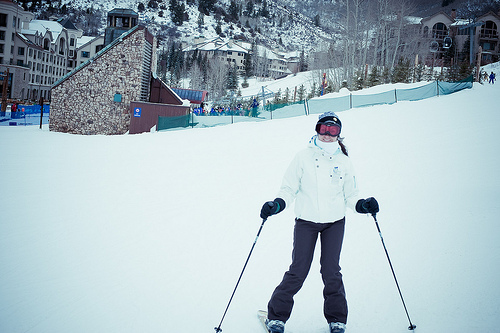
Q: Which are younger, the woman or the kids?
A: The kids are younger than the woman.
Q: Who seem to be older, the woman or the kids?
A: The woman are older than the kids.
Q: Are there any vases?
A: No, there are no vases.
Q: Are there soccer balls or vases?
A: No, there are no vases or soccer balls.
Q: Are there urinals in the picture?
A: No, there are no urinals.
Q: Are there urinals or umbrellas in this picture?
A: No, there are no urinals or umbrellas.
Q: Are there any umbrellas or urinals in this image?
A: No, there are no urinals or umbrellas.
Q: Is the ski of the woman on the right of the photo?
A: Yes, the ski is on the right of the image.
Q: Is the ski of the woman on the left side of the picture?
A: No, the ski is on the right of the image.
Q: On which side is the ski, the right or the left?
A: The ski is on the right of the image.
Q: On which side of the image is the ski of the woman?
A: The ski is on the right of the image.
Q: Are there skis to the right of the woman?
A: Yes, there is a ski to the right of the woman.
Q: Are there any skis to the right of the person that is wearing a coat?
A: Yes, there is a ski to the right of the woman.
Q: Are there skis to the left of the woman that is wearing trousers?
A: No, the ski is to the right of the woman.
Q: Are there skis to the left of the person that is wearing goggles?
A: No, the ski is to the right of the woman.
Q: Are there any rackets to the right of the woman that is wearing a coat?
A: No, there is a ski to the right of the woman.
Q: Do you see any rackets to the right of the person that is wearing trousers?
A: No, there is a ski to the right of the woman.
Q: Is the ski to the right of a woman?
A: Yes, the ski is to the right of a woman.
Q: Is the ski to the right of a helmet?
A: No, the ski is to the right of a woman.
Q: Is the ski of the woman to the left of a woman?
A: No, the ski is to the right of a woman.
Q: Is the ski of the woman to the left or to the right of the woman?
A: The ski is to the right of the woman.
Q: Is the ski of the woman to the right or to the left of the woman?
A: The ski is to the right of the woman.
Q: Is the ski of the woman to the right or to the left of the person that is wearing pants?
A: The ski is to the right of the woman.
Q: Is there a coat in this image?
A: Yes, there is a coat.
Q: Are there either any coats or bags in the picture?
A: Yes, there is a coat.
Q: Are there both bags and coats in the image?
A: No, there is a coat but no bags.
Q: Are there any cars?
A: No, there are no cars.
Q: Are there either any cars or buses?
A: No, there are no cars or buses.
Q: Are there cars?
A: No, there are no cars.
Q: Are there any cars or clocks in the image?
A: No, there are no cars or clocks.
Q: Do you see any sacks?
A: No, there are no sacks.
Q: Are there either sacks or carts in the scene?
A: No, there are no sacks or carts.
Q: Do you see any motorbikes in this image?
A: No, there are no motorbikes.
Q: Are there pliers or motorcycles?
A: No, there are no motorcycles or pliers.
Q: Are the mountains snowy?
A: Yes, the mountains are snowy.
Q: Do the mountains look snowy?
A: Yes, the mountains are snowy.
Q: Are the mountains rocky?
A: No, the mountains are snowy.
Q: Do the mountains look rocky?
A: No, the mountains are snowy.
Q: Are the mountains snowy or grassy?
A: The mountains are snowy.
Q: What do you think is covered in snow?
A: The mountains are covered in snow.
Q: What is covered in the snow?
A: The mountains are covered in snow.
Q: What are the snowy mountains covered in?
A: The mountains are covered in snow.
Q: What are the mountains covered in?
A: The mountains are covered in snow.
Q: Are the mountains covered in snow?
A: Yes, the mountains are covered in snow.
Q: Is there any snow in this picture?
A: Yes, there is snow.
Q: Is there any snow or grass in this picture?
A: Yes, there is snow.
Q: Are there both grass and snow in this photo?
A: No, there is snow but no grass.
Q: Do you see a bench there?
A: No, there are no benches.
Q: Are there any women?
A: Yes, there is a woman.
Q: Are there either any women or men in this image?
A: Yes, there is a woman.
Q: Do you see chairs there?
A: No, there are no chairs.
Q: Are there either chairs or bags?
A: No, there are no chairs or bags.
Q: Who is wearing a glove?
A: The woman is wearing a glove.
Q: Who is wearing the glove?
A: The woman is wearing a glove.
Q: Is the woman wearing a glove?
A: Yes, the woman is wearing a glove.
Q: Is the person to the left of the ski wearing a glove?
A: Yes, the woman is wearing a glove.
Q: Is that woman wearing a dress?
A: No, the woman is wearing a glove.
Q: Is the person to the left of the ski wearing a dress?
A: No, the woman is wearing a glove.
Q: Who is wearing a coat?
A: The woman is wearing a coat.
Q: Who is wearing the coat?
A: The woman is wearing a coat.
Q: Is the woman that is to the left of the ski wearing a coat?
A: Yes, the woman is wearing a coat.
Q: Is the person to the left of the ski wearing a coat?
A: Yes, the woman is wearing a coat.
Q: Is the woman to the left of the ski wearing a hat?
A: No, the woman is wearing a coat.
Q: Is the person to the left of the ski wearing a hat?
A: No, the woman is wearing a coat.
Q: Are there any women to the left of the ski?
A: Yes, there is a woman to the left of the ski.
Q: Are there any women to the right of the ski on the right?
A: No, the woman is to the left of the ski.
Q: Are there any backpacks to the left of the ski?
A: No, there is a woman to the left of the ski.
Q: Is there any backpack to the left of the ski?
A: No, there is a woman to the left of the ski.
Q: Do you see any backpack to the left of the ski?
A: No, there is a woman to the left of the ski.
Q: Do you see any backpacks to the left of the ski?
A: No, there is a woman to the left of the ski.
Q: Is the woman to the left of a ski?
A: Yes, the woman is to the left of a ski.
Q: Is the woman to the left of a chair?
A: No, the woman is to the left of a ski.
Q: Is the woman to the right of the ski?
A: No, the woman is to the left of the ski.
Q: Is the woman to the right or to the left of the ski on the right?
A: The woman is to the left of the ski.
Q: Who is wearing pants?
A: The woman is wearing pants.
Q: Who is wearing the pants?
A: The woman is wearing pants.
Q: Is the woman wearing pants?
A: Yes, the woman is wearing pants.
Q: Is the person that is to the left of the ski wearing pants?
A: Yes, the woman is wearing pants.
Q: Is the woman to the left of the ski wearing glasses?
A: No, the woman is wearing pants.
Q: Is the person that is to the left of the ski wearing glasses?
A: No, the woman is wearing pants.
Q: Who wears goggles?
A: The woman wears goggles.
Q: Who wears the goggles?
A: The woman wears goggles.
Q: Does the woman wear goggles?
A: Yes, the woman wears goggles.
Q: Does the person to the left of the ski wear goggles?
A: Yes, the woman wears goggles.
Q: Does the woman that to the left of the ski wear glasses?
A: No, the woman wears goggles.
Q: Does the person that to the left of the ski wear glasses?
A: No, the woman wears goggles.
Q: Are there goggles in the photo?
A: Yes, there are goggles.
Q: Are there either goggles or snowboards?
A: Yes, there are goggles.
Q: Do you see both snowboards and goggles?
A: No, there are goggles but no snowboards.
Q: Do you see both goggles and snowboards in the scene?
A: No, there are goggles but no snowboards.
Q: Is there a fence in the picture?
A: Yes, there is a fence.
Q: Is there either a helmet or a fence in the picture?
A: Yes, there is a fence.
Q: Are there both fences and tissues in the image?
A: No, there is a fence but no tissues.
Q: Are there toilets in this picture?
A: No, there are no toilets.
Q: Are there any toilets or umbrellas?
A: No, there are no toilets or umbrellas.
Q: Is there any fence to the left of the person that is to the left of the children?
A: Yes, there is a fence to the left of the person.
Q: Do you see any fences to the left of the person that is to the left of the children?
A: Yes, there is a fence to the left of the person.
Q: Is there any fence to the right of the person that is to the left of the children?
A: No, the fence is to the left of the person.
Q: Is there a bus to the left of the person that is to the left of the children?
A: No, there is a fence to the left of the person.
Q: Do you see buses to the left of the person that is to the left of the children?
A: No, there is a fence to the left of the person.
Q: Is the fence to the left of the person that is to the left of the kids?
A: Yes, the fence is to the left of the person.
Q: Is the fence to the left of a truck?
A: No, the fence is to the left of the person.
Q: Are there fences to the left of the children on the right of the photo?
A: Yes, there is a fence to the left of the kids.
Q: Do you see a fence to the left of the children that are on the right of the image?
A: Yes, there is a fence to the left of the kids.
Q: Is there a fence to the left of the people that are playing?
A: Yes, there is a fence to the left of the kids.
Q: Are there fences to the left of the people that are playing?
A: Yes, there is a fence to the left of the kids.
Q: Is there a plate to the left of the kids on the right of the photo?
A: No, there is a fence to the left of the kids.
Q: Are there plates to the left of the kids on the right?
A: No, there is a fence to the left of the kids.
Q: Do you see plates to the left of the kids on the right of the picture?
A: No, there is a fence to the left of the kids.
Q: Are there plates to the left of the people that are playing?
A: No, there is a fence to the left of the kids.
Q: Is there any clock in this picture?
A: No, there are no clocks.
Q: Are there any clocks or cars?
A: No, there are no clocks or cars.